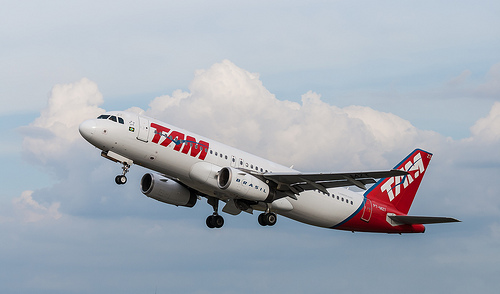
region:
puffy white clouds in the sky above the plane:
[168, 45, 353, 124]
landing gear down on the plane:
[113, 148, 134, 191]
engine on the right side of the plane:
[214, 163, 274, 205]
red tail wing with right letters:
[363, 136, 438, 236]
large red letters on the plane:
[149, 118, 217, 160]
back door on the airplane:
[357, 195, 376, 226]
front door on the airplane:
[136, 109, 151, 147]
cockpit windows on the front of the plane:
[96, 109, 124, 128]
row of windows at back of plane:
[329, 188, 357, 206]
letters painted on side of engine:
[230, 174, 272, 196]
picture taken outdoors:
[28, 16, 436, 291]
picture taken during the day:
[66, 76, 411, 292]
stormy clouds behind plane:
[54, 74, 469, 176]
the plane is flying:
[103, 101, 495, 264]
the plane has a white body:
[108, 106, 338, 227]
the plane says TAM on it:
[143, 117, 210, 157]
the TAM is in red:
[139, 119, 212, 159]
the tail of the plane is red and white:
[353, 121, 453, 258]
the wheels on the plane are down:
[116, 168, 298, 231]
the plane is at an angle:
[66, 103, 460, 259]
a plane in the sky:
[81, 77, 498, 289]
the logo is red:
[145, 120, 222, 162]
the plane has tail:
[341, 105, 459, 290]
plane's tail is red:
[338, 103, 443, 292]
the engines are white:
[130, 132, 288, 236]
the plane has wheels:
[85, 156, 282, 260]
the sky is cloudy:
[82, 80, 395, 177]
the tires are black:
[88, 183, 337, 284]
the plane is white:
[133, 98, 378, 227]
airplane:
[80, 109, 414, 262]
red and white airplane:
[74, 96, 456, 254]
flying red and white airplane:
[82, 102, 444, 245]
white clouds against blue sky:
[4, 16, 110, 86]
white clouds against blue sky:
[11, 59, 76, 196]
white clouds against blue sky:
[11, 183, 104, 263]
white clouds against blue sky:
[108, 28, 268, 92]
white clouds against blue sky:
[222, 51, 379, 130]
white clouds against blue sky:
[353, 28, 488, 143]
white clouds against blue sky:
[263, 237, 498, 273]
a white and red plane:
[74, 100, 464, 240]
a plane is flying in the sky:
[71, 102, 467, 240]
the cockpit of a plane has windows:
[73, 100, 138, 161]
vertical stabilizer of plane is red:
[362, 143, 437, 212]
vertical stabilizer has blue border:
[362, 145, 441, 207]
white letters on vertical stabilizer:
[362, 143, 439, 213]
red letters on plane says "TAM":
[143, 115, 214, 165]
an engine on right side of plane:
[214, 163, 274, 205]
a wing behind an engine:
[253, 163, 414, 191]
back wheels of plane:
[203, 200, 285, 234]